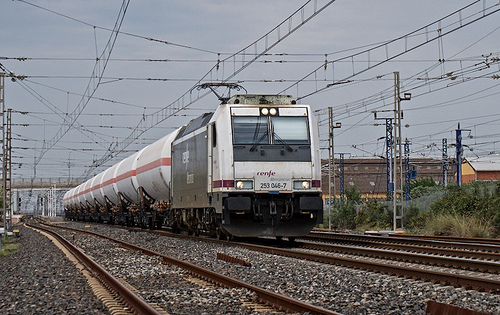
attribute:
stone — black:
[308, 278, 314, 282]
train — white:
[34, 104, 334, 235]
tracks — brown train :
[278, 211, 454, 288]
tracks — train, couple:
[340, 244, 470, 298]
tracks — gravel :
[276, 230, 446, 303]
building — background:
[330, 144, 483, 204]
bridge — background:
[4, 172, 109, 197]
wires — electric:
[11, 10, 480, 176]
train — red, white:
[60, 82, 330, 237]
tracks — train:
[25, 209, 308, 304]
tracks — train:
[279, 229, 467, 289]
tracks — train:
[319, 212, 479, 250]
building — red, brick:
[322, 155, 469, 207]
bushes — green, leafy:
[328, 175, 482, 226]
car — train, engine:
[168, 75, 336, 239]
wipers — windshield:
[269, 119, 295, 159]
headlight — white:
[298, 177, 310, 194]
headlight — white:
[234, 177, 254, 190]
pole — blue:
[371, 107, 403, 208]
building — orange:
[458, 150, 482, 190]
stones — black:
[299, 288, 350, 313]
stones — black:
[317, 292, 365, 311]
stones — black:
[317, 284, 342, 313]